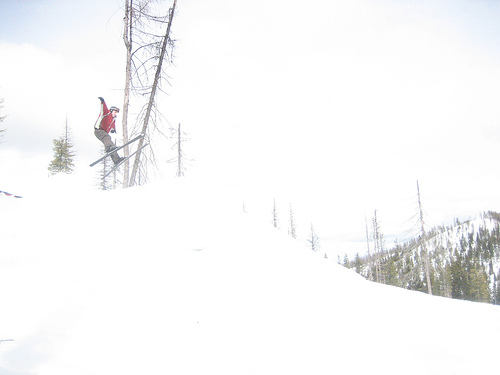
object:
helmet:
[109, 105, 120, 113]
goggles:
[110, 107, 120, 111]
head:
[109, 106, 120, 119]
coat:
[94, 102, 117, 134]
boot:
[110, 152, 128, 164]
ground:
[0, 278, 300, 375]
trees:
[367, 210, 497, 302]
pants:
[94, 128, 121, 163]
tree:
[122, 0, 173, 191]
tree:
[47, 111, 77, 174]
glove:
[97, 96, 105, 102]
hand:
[97, 96, 105, 102]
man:
[93, 96, 127, 164]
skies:
[0, 0, 500, 179]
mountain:
[338, 210, 499, 306]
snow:
[0, 174, 500, 375]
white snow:
[418, 313, 470, 354]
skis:
[89, 135, 150, 180]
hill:
[0, 172, 310, 375]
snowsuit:
[89, 101, 126, 162]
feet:
[104, 146, 118, 154]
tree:
[93, 139, 124, 190]